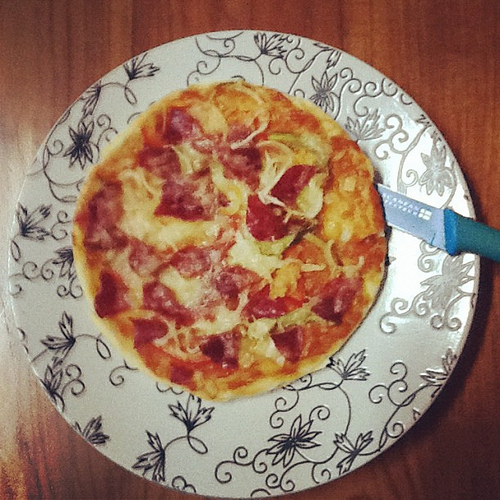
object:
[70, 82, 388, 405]
pizza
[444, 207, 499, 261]
handle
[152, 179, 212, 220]
pepperoni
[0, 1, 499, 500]
table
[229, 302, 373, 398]
crust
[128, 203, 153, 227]
cheese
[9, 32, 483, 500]
plate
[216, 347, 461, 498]
design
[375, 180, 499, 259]
knife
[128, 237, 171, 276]
pepperoni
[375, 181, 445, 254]
blade